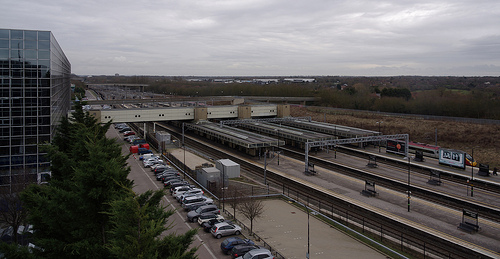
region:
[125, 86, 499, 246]
the entrance for trains to a train station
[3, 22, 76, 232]
a tall office building with mirrored windows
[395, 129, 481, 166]
a speed train on the tracks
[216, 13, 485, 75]
a very grey sky with many clouds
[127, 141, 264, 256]
a row of parked cars at the station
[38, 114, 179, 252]
several tall green trees next to the building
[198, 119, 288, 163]
a metal awning covering the platform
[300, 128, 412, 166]
a grey lighting structure outside the station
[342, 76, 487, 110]
trees and fields in the distance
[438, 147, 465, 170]
a large advertising sign on the platform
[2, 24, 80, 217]
a building with lots of windows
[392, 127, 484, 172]
a train on a track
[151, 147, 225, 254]
cars parked in a parking lot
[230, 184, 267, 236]
trees in the parking lot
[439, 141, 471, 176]
a sign next to the train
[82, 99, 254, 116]
a bridge connecting trains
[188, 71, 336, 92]
buildings in the background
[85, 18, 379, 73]
a cloudy day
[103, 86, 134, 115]
a track for the train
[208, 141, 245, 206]
electrical boxes for the building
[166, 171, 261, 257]
Cars parked in parking area.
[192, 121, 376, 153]
Three train terminals.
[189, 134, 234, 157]
A train railroad track.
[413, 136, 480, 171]
Red and yellow train moving on track.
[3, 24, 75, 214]
Building across from train terminals.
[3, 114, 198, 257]
Tree growing next to parking area.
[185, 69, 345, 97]
Buildings out in the distance.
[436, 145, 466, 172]
A sign on side of train tracks.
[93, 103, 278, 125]
Walkway building above ground.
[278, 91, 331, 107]
Overpass above a road.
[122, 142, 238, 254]
Cars are parked in a row.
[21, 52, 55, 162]
A lot of windows on the building.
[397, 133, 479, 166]
A train on the track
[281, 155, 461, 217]
The train station is empty.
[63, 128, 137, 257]
The trees are green.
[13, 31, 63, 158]
The building is made of glass.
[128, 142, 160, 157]
The red car is parked.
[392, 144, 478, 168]
The train is red and white.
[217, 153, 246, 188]
A small white building is by the tracks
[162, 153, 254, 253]
A lot of cars are parked by the gate.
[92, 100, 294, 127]
a bridge above the freeway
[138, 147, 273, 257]
a long line of cars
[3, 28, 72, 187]
a big glass building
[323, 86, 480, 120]
a line of trees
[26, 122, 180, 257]
tall dark green trees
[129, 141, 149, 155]
a red container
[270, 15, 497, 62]
a sky with grey clouds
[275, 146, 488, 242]
the streets for cars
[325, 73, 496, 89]
a short hill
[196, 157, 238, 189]
two cargo containers